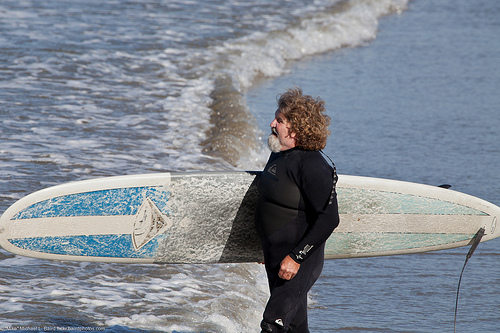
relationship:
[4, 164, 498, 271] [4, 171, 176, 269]
surf board en blue and white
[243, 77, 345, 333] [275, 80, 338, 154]
man has curly hair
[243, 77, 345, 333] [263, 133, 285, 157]
man has beard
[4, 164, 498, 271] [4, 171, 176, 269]
surf board en aqua and white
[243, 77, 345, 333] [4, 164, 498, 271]
man carrying surf board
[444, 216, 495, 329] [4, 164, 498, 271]
tether attached to surf board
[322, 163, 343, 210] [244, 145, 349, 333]
tie hangs from suit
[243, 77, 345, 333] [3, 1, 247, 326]
man walking into ocean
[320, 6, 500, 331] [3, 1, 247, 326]
beach next ocean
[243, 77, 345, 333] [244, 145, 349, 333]
man wears wetsuit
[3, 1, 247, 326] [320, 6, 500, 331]
ocean near beach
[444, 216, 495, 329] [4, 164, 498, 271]
cord end of surfboard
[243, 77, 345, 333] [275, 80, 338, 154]
man has long hair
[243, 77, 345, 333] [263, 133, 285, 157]
man has facial hair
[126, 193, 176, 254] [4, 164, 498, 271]
logo on surfboard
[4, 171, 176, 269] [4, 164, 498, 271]
front of surfboard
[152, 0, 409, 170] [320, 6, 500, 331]
wave in sand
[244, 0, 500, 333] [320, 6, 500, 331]
beach in sand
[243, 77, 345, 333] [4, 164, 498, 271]
man holds board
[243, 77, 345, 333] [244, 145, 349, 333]
man wearing wet suit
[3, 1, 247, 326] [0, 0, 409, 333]
water has ocean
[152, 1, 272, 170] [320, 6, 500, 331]
wave rolling into shore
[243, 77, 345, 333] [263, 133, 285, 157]
man with goatee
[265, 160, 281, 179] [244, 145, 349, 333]
logo on wetsuit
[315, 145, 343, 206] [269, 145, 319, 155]
strap runs from neck